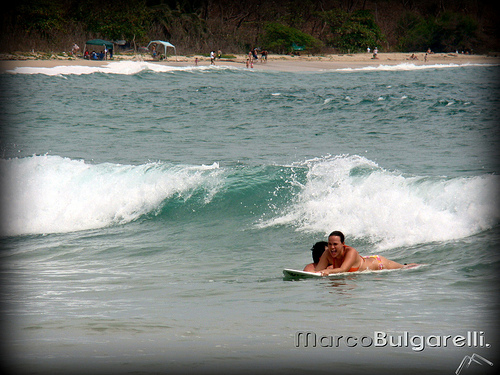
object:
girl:
[311, 230, 423, 278]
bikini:
[331, 245, 385, 272]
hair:
[328, 229, 346, 244]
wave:
[242, 151, 500, 255]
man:
[303, 240, 328, 272]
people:
[194, 56, 200, 66]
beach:
[0, 52, 500, 76]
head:
[326, 230, 345, 258]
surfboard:
[281, 264, 431, 282]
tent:
[145, 40, 179, 61]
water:
[0, 62, 500, 375]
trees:
[247, 21, 330, 56]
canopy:
[81, 38, 114, 62]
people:
[216, 47, 223, 61]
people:
[209, 50, 216, 66]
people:
[249, 61, 254, 69]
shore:
[0, 53, 500, 78]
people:
[244, 58, 249, 69]